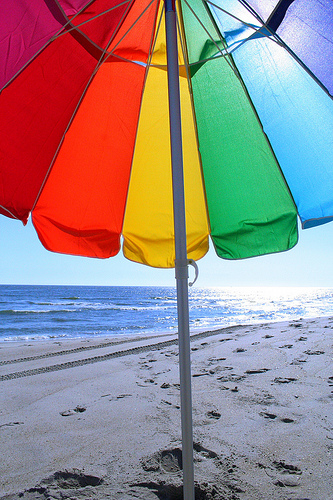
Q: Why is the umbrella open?
A: To block the sun.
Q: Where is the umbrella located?
A: On a beach.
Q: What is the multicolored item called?
A: An umbrella.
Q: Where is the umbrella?
A: On a pole.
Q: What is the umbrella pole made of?
A: Metal.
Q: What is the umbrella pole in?
A: Sand.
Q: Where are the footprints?
A: In the sand.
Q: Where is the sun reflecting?
A: Water.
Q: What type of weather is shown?
A: Sunny.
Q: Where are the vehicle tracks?
A: Next to the water.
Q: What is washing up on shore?
A: Water.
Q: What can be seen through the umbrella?
A: Sun.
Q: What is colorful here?
A: An umbrella.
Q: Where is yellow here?
A: On the umbrella.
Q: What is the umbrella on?
A: A pole.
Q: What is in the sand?
A: Footprints.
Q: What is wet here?
A: The sand.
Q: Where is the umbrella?
A: On the beach.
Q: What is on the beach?
A: An umbrella.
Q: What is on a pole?
A: An umbrella.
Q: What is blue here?
A: The ocean.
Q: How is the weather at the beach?
A: Sunshine.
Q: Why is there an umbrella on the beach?
A: For shade.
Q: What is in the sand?
A: An umbrella.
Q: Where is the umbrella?
A: In the sand.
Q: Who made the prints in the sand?
A: People at the beach.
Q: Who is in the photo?
A: Nobody.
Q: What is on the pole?
A: An umbrella.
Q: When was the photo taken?
A: Daytime.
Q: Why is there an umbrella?
A: For shade.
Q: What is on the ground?
A: Sand.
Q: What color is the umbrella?
A: Rainbow.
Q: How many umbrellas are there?
A: One.